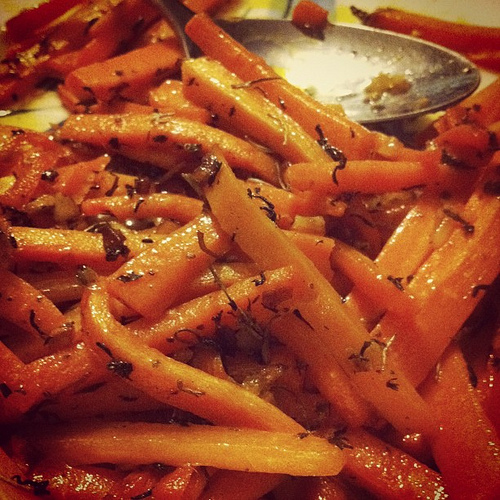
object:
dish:
[0, 89, 72, 133]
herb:
[190, 153, 222, 188]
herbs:
[81, 217, 140, 265]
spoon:
[146, 0, 480, 124]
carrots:
[363, 71, 411, 105]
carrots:
[0, 0, 500, 500]